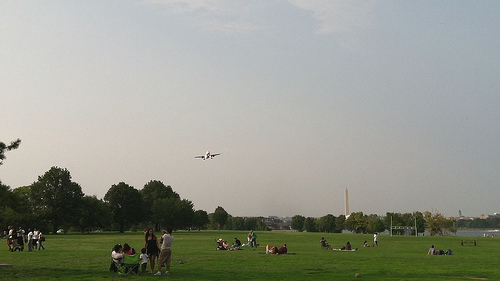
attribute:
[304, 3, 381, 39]
clouds — white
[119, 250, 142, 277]
chair — green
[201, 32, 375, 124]
sky — blue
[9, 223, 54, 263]
people — group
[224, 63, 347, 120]
sky — gray, cloudy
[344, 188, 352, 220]
monument — Washington monument, pointy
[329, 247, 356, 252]
blanket — white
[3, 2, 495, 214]
sky — blue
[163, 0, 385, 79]
clouds/sky — WHITE, BLUE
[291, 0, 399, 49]
clouds — white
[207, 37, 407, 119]
sky — blue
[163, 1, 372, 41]
cloud — white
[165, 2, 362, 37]
cloud — white